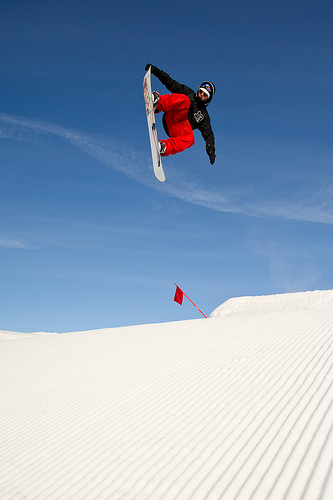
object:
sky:
[2, 2, 327, 336]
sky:
[0, 0, 205, 321]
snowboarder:
[141, 64, 216, 182]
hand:
[145, 63, 151, 72]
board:
[141, 64, 166, 183]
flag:
[173, 283, 209, 320]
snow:
[1, 288, 332, 498]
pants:
[154, 90, 195, 159]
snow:
[5, 326, 331, 409]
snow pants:
[155, 92, 194, 156]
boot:
[156, 139, 168, 160]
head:
[192, 77, 219, 109]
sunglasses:
[197, 88, 209, 98]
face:
[193, 85, 210, 103]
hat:
[199, 84, 213, 99]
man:
[140, 60, 218, 185]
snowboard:
[140, 61, 169, 189]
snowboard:
[141, 64, 166, 182]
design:
[142, 75, 150, 107]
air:
[62, 32, 289, 244]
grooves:
[4, 307, 332, 498]